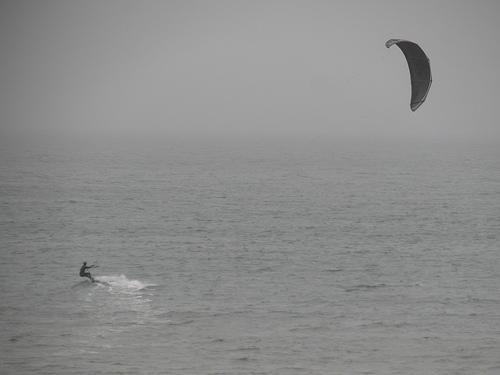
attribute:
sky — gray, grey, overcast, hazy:
[1, 1, 498, 150]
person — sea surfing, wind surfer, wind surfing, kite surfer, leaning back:
[78, 261, 95, 282]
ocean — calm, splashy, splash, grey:
[1, 144, 500, 374]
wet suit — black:
[78, 265, 92, 278]